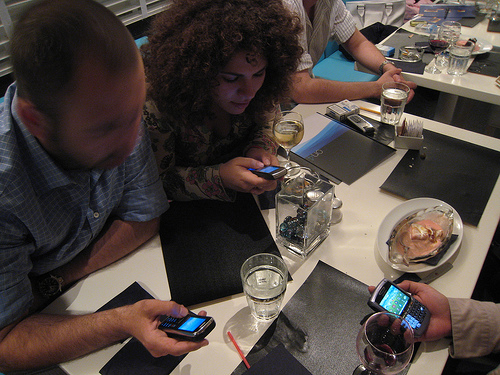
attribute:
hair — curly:
[150, 8, 301, 128]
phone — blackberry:
[359, 278, 474, 358]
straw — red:
[210, 305, 267, 371]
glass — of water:
[355, 73, 416, 163]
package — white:
[314, 93, 375, 146]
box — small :
[393, 117, 430, 147]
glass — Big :
[362, 314, 424, 372]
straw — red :
[228, 330, 259, 373]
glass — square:
[276, 171, 330, 258]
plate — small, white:
[378, 196, 462, 273]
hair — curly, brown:
[140, 1, 303, 142]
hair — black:
[7, 1, 140, 152]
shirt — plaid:
[1, 80, 164, 322]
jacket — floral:
[138, 68, 283, 199]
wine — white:
[276, 120, 304, 150]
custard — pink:
[396, 218, 443, 258]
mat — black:
[230, 259, 419, 372]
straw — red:
[225, 326, 250, 370]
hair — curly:
[216, 18, 266, 38]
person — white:
[15, 5, 173, 164]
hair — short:
[56, 31, 94, 51]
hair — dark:
[52, 19, 101, 53]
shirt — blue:
[11, 156, 123, 261]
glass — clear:
[234, 250, 299, 343]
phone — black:
[168, 307, 205, 341]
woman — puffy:
[188, 19, 268, 114]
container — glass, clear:
[252, 167, 335, 252]